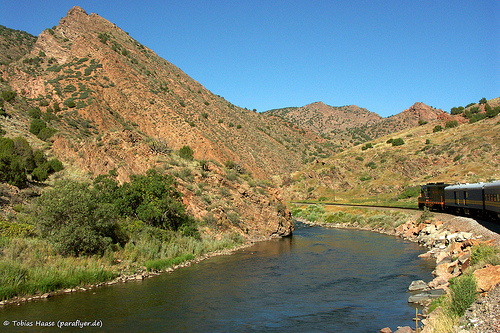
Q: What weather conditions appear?
A: It is clear.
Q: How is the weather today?
A: It is clear.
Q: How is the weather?
A: It is clear.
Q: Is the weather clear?
A: Yes, it is clear.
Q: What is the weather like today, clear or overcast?
A: It is clear.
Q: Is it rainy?
A: No, it is clear.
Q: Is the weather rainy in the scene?
A: No, it is clear.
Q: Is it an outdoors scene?
A: Yes, it is outdoors.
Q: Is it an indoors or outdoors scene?
A: It is outdoors.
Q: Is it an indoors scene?
A: No, it is outdoors.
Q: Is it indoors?
A: No, it is outdoors.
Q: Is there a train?
A: Yes, there is a train.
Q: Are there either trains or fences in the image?
A: Yes, there is a train.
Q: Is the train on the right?
A: Yes, the train is on the right of the image.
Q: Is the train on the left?
A: No, the train is on the right of the image.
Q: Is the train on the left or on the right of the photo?
A: The train is on the right of the image.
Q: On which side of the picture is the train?
A: The train is on the right of the image.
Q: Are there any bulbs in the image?
A: No, there are no bulbs.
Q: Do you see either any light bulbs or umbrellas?
A: No, there are no light bulbs or umbrellas.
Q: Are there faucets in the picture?
A: No, there are no faucets.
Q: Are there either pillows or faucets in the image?
A: No, there are no faucets or pillows.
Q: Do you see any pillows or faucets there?
A: No, there are no faucets or pillows.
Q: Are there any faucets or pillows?
A: No, there are no faucets or pillows.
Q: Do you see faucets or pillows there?
A: No, there are no faucets or pillows.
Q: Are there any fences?
A: No, there are no fences.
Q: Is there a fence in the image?
A: No, there are no fences.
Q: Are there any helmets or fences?
A: No, there are no fences or helmets.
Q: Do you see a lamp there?
A: No, there are no lamps.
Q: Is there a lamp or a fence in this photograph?
A: No, there are no lamps or fences.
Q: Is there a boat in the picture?
A: No, there are no boats.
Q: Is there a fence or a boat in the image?
A: No, there are no boats or fences.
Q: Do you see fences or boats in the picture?
A: No, there are no boats or fences.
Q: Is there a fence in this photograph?
A: No, there are no fences.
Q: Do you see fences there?
A: No, there are no fences.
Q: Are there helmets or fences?
A: No, there are no fences or helmets.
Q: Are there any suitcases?
A: No, there are no suitcases.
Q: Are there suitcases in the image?
A: No, there are no suitcases.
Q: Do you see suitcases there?
A: No, there are no suitcases.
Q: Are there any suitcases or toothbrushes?
A: No, there are no suitcases or toothbrushes.